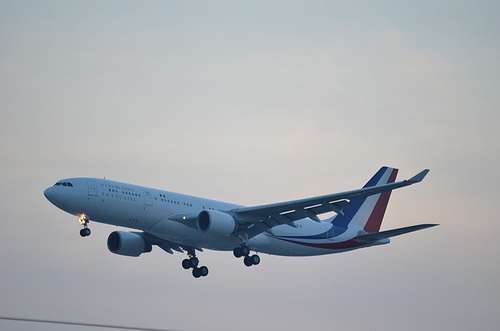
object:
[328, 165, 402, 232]
tail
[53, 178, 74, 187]
windshield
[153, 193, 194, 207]
windows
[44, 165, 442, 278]
airplane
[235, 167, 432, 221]
wing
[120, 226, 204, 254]
wing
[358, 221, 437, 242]
wing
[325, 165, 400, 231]
wing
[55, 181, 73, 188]
window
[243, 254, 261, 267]
back wheel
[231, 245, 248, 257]
back wheel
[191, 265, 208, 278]
back wheel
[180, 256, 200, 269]
back wheel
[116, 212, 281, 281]
gear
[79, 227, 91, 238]
wheel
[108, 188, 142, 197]
windows